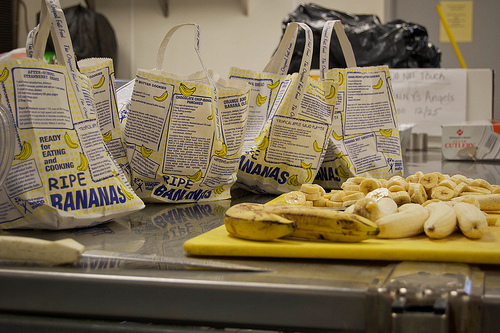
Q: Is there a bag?
A: Yes, there is a bag.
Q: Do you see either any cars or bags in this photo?
A: Yes, there is a bag.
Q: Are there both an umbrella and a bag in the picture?
A: No, there is a bag but no umbrellas.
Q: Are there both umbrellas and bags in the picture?
A: No, there is a bag but no umbrellas.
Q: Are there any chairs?
A: No, there are no chairs.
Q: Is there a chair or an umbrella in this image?
A: No, there are no chairs or umbrellas.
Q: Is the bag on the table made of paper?
A: Yes, the bag is made of paper.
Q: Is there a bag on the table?
A: Yes, there is a bag on the table.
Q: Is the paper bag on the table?
A: Yes, the bag is on the table.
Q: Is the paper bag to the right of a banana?
A: No, the bag is to the left of a banana.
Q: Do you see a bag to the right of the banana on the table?
A: No, the bag is to the left of the banana.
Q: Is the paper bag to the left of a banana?
A: Yes, the bag is to the left of a banana.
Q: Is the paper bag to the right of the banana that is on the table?
A: No, the bag is to the left of the banana.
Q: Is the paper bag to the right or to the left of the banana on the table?
A: The bag is to the left of the banana.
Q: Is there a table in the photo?
A: Yes, there is a table.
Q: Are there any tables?
A: Yes, there is a table.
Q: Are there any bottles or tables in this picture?
A: Yes, there is a table.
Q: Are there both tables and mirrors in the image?
A: No, there is a table but no mirrors.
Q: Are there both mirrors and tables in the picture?
A: No, there is a table but no mirrors.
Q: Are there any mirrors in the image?
A: No, there are no mirrors.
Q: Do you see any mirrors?
A: No, there are no mirrors.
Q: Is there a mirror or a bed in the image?
A: No, there are no mirrors or beds.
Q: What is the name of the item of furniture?
A: The piece of furniture is a table.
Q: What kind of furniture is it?
A: The piece of furniture is a table.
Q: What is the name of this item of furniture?
A: This is a table.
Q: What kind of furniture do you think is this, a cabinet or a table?
A: This is a table.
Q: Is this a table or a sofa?
A: This is a table.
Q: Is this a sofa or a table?
A: This is a table.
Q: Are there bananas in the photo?
A: Yes, there is a banana.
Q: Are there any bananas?
A: Yes, there is a banana.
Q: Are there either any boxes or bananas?
A: Yes, there is a banana.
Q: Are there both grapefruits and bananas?
A: No, there is a banana but no grapefruits.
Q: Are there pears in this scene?
A: No, there are no pears.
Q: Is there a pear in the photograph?
A: No, there are no pears.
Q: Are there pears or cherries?
A: No, there are no pears or cherries.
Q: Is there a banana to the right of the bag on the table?
A: Yes, there is a banana to the right of the bag.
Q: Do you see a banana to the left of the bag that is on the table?
A: No, the banana is to the right of the bag.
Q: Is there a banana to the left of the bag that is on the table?
A: No, the banana is to the right of the bag.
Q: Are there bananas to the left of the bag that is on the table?
A: No, the banana is to the right of the bag.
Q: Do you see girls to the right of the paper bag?
A: No, there is a banana to the right of the bag.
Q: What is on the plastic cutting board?
A: The banana is on the cutting board.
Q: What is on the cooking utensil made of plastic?
A: The banana is on the cutting board.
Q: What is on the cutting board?
A: The banana is on the cutting board.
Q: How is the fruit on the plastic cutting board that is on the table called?
A: The fruit is a banana.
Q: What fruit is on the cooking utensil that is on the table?
A: The fruit is a banana.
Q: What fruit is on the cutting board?
A: The fruit is a banana.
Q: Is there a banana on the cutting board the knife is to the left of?
A: Yes, there is a banana on the cutting board.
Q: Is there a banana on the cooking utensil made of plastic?
A: Yes, there is a banana on the cutting board.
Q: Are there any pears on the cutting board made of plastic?
A: No, there is a banana on the cutting board.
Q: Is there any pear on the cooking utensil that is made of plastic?
A: No, there is a banana on the cutting board.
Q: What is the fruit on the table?
A: The fruit is a banana.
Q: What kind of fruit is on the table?
A: The fruit is a banana.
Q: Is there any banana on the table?
A: Yes, there is a banana on the table.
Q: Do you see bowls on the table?
A: No, there is a banana on the table.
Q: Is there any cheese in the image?
A: No, there is no cheese.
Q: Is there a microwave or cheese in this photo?
A: No, there are no cheese or microwaves.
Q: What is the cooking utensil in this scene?
A: The cooking utensil is a cutting board.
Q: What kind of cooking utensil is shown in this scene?
A: The cooking utensil is a cutting board.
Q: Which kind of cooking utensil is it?
A: The cooking utensil is a cutting board.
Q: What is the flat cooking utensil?
A: The cooking utensil is a cutting board.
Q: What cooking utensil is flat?
A: The cooking utensil is a cutting board.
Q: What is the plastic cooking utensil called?
A: The cooking utensil is a cutting board.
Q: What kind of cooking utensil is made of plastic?
A: The cooking utensil is a cutting board.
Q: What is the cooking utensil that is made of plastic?
A: The cooking utensil is a cutting board.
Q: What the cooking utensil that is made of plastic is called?
A: The cooking utensil is a cutting board.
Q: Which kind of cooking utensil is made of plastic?
A: The cooking utensil is a cutting board.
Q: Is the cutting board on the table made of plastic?
A: Yes, the cutting board is made of plastic.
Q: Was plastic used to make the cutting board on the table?
A: Yes, the cutting board is made of plastic.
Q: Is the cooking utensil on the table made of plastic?
A: Yes, the cutting board is made of plastic.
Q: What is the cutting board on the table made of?
A: The cutting board is made of plastic.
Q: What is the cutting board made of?
A: The cutting board is made of plastic.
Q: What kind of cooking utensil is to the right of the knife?
A: The cooking utensil is a cutting board.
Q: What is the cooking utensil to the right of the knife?
A: The cooking utensil is a cutting board.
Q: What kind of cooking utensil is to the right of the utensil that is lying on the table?
A: The cooking utensil is a cutting board.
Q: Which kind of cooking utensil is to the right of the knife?
A: The cooking utensil is a cutting board.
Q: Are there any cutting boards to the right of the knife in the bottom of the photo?
A: Yes, there is a cutting board to the right of the knife.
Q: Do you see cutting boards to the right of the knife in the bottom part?
A: Yes, there is a cutting board to the right of the knife.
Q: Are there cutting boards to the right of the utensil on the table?
A: Yes, there is a cutting board to the right of the knife.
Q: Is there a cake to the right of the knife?
A: No, there is a cutting board to the right of the knife.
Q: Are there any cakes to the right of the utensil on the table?
A: No, there is a cutting board to the right of the knife.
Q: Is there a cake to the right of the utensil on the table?
A: No, there is a cutting board to the right of the knife.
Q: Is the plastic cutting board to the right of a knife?
A: Yes, the cutting board is to the right of a knife.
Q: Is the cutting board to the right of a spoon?
A: No, the cutting board is to the right of a knife.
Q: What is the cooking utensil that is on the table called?
A: The cooking utensil is a cutting board.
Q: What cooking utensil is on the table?
A: The cooking utensil is a cutting board.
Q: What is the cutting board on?
A: The cutting board is on the table.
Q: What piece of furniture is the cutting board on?
A: The cutting board is on the table.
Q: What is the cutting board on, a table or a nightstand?
A: The cutting board is on a table.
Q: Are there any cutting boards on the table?
A: Yes, there is a cutting board on the table.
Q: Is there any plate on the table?
A: No, there is a cutting board on the table.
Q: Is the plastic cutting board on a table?
A: Yes, the cutting board is on a table.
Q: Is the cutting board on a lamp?
A: No, the cutting board is on a table.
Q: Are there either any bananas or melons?
A: Yes, there is a banana.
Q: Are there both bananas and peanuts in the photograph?
A: No, there is a banana but no peanuts.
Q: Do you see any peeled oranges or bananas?
A: Yes, there is a peeled banana.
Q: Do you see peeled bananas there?
A: Yes, there is a peeled banana.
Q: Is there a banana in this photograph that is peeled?
A: Yes, there is a banana that is peeled.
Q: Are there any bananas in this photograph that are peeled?
A: Yes, there is a banana that is peeled.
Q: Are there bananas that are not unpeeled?
A: Yes, there is an peeled banana.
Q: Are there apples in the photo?
A: No, there are no apples.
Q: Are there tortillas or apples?
A: No, there are no apples or tortillas.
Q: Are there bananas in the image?
A: Yes, there is a banana.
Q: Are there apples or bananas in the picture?
A: Yes, there is a banana.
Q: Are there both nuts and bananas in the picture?
A: No, there is a banana but no nuts.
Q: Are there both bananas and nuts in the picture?
A: No, there is a banana but no nuts.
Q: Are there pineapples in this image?
A: No, there are no pineapples.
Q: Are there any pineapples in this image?
A: No, there are no pineapples.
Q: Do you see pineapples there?
A: No, there are no pineapples.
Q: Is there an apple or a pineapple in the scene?
A: No, there are no pineapples or apples.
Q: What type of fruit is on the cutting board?
A: The fruit is a banana.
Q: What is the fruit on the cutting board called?
A: The fruit is a banana.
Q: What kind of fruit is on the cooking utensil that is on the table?
A: The fruit is a banana.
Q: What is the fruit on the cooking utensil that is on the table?
A: The fruit is a banana.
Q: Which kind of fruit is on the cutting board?
A: The fruit is a banana.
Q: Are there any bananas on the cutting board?
A: Yes, there is a banana on the cutting board.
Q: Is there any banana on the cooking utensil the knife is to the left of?
A: Yes, there is a banana on the cutting board.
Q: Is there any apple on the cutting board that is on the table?
A: No, there is a banana on the cutting board.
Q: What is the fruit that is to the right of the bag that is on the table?
A: The fruit is a banana.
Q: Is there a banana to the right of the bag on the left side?
A: Yes, there is a banana to the right of the bag.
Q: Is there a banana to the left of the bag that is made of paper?
A: No, the banana is to the right of the bag.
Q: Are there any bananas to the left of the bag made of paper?
A: No, the banana is to the right of the bag.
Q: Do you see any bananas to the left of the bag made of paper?
A: No, the banana is to the right of the bag.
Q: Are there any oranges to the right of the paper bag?
A: No, there is a banana to the right of the bag.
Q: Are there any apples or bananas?
A: Yes, there is a banana.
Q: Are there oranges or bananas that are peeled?
A: Yes, the banana is peeled.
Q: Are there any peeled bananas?
A: Yes, there is a peeled banana.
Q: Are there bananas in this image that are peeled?
A: Yes, there is a banana that is peeled.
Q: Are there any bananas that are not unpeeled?
A: Yes, there is an peeled banana.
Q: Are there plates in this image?
A: No, there are no plates.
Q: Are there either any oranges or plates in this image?
A: No, there are no plates or oranges.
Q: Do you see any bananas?
A: Yes, there is a banana.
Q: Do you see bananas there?
A: Yes, there is a banana.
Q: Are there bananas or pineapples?
A: Yes, there is a banana.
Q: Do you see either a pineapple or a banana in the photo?
A: Yes, there is a banana.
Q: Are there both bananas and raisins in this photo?
A: No, there is a banana but no raisins.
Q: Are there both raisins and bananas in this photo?
A: No, there is a banana but no raisins.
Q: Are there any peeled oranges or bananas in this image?
A: Yes, there is a peeled banana.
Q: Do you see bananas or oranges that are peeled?
A: Yes, the banana is peeled.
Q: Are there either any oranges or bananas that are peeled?
A: Yes, the banana is peeled.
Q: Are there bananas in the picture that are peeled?
A: Yes, there is a peeled banana.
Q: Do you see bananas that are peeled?
A: Yes, there is a banana that is peeled.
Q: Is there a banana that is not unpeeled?
A: Yes, there is an peeled banana.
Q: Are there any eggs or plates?
A: No, there are no plates or eggs.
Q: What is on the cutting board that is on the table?
A: The banana is on the cutting board.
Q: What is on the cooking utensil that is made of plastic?
A: The banana is on the cutting board.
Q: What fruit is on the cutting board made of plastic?
A: The fruit is a banana.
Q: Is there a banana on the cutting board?
A: Yes, there is a banana on the cutting board.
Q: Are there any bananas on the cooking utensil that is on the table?
A: Yes, there is a banana on the cutting board.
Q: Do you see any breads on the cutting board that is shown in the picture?
A: No, there is a banana on the cutting board.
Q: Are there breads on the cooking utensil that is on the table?
A: No, there is a banana on the cutting board.